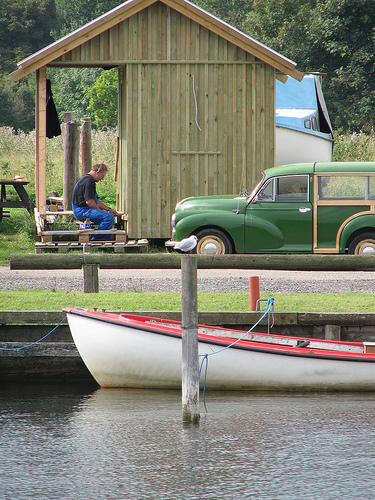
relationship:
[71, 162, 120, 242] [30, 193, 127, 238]
carpenter on bench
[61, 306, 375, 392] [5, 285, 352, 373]
boat at shore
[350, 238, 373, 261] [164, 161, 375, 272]
wheel of car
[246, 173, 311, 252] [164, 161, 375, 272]
door of car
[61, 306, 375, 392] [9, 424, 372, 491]
boat in water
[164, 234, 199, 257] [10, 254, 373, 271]
bird in rail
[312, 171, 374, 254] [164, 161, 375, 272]
wood in car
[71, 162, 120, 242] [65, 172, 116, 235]
carpenter over overalls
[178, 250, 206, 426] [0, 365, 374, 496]
post in water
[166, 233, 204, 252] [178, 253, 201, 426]
bird in post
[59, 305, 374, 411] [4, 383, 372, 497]
boat in water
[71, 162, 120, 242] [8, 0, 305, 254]
carpenter working on building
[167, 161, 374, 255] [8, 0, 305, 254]
car parked by building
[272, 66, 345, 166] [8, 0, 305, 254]
boat behind building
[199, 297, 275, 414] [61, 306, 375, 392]
blue rope securing boat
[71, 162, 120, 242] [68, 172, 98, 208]
carpenter wearing shirt